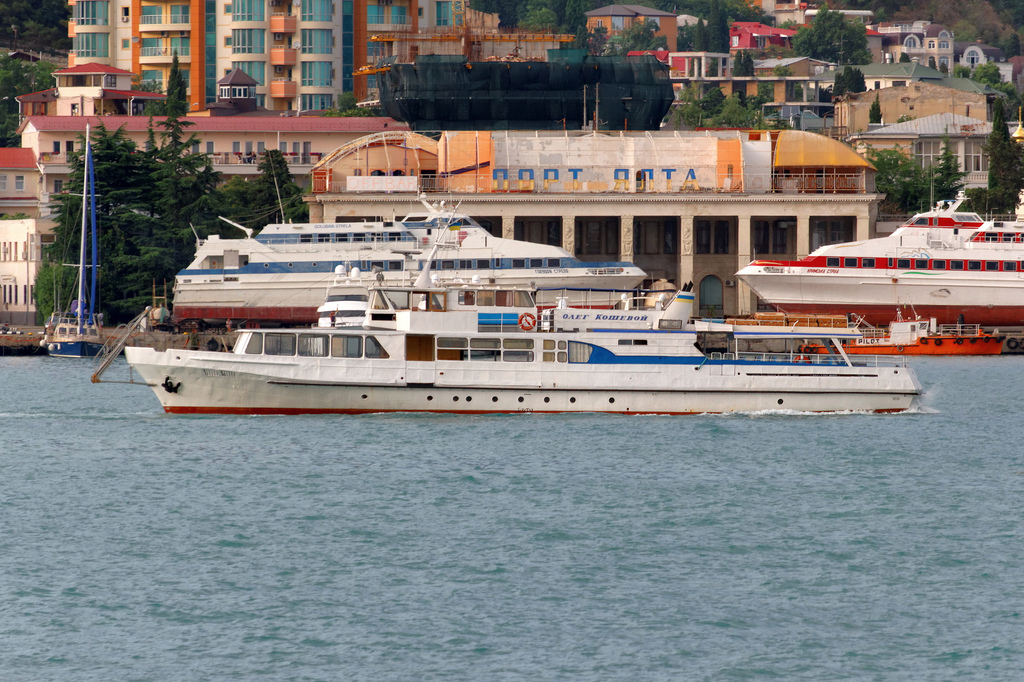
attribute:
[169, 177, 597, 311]
yacht — large, white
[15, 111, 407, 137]
roof — reddish brown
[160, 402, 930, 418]
bottom — red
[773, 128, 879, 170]
roof — yellow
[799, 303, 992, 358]
boat — orange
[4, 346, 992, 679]
water — blue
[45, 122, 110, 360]
boat — blue, white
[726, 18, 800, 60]
house — red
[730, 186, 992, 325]
boat — big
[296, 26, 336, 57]
window — closed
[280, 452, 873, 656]
water — blue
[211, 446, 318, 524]
water — blue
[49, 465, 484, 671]
water — blue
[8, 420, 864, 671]
water — blue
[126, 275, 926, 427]
boat — white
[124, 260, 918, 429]
boat — white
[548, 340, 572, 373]
window — white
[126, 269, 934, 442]
boat — large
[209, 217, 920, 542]
boat — white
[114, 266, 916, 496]
sailboat — blue 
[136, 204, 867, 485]
boat — long , white 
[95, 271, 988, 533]
boat — white , large , red 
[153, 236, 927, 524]
boat — white, blue, large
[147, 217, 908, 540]
boat — blue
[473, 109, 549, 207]
letters — blue, yellow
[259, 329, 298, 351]
boat — window 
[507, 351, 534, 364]
boat — window 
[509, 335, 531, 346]
boat — window 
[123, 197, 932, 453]
boat —  long in size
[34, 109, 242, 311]
tree — green 